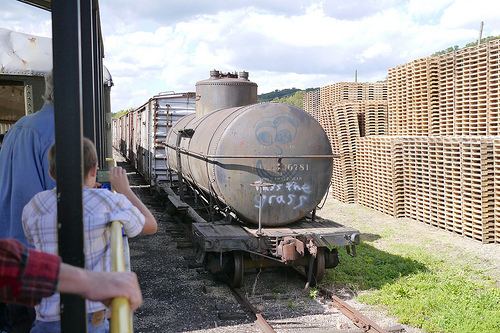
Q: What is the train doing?
A: Departing.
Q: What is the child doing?
A: Taking a picture.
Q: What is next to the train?
A: Stacks of pallets.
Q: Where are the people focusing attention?
A: At the antique train sitting on the right.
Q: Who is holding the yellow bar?
A: A man with a hairy arm.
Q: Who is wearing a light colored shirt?
A: The boy with short brown hair.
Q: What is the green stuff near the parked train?
A: It is green grass.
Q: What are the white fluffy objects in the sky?
A: They are clouds.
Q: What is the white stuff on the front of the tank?
A: It is white writing.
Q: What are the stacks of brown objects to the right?
A: They are stacks of wooden pallets.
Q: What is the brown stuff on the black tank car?
A: It is mostly rust.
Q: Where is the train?
A: On the tracks.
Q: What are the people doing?
A: Standing.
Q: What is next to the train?
A: Pallets.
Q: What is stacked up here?
A: Pallets.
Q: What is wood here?
A: Pallets.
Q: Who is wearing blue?
A: A man.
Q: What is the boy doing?
A: Taking a picture.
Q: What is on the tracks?
A: A train.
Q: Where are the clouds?
A: In the sky.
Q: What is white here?
A: Clouds.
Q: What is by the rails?
A: Green grass growing by rails.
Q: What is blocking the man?
A: Metal pole block man with phone.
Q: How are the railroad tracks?
A: Rusted railroad tracks on ground.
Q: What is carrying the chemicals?
A: Black train car for carrying chemicals.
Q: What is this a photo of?
A: A train.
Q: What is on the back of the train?
A: A smiley face.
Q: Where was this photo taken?
A: Outside.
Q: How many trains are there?
A: 1.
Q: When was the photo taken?
A: During the day.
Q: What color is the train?
A: Black.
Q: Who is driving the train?
A: A conductor.